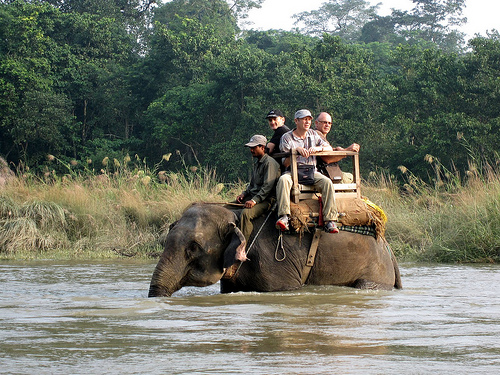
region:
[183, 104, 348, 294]
Four men riding an elephant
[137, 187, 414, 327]
The elephant is walking through water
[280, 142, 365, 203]
This is a wood structure atop an elephant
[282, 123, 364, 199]
The people riding the elephant are inside of the wood structure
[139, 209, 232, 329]
The elephants trunk is in the water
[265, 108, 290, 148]
This man is wearing a black shirt and ball cap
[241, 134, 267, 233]
This man is steering the elephant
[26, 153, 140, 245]
The weeds are tall and brown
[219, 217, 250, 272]
The elephants left ear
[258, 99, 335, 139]
The men are looking the same direction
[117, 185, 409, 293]
An elephant in the water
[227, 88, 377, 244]
4 men riding the elephant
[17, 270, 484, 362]
The water is calm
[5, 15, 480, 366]
Photo taken during the day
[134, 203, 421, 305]
The elephant is grayish brown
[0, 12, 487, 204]
Green leaves on the trees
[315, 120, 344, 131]
Glasses on the man's face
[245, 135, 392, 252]
Wooden saddle on the elephant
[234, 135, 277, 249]
Man navigating the elephant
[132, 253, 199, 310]
Elephant's trunk in the water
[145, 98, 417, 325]
An elephant in water.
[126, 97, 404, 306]
An elephant giving passengers a ride across the water.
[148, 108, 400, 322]
Three passengers ride an elephant.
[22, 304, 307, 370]
A body of water.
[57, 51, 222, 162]
A wooded area.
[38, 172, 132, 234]
The tall grass.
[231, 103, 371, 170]
Three out of four men wearing hats.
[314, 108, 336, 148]
A man wearing glasses.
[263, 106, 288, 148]
A man wearing a black hat.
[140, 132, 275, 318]
A man steering an elephant in the water.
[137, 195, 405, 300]
Large elephant in water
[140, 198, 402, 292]
Large elephant is wet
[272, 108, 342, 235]
Man wearing gray hat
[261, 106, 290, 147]
Man wearing black hat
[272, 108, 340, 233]
Man carrying black briefcase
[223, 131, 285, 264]
Man wearing green pants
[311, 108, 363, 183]
Man holding onto wooden crate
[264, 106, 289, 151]
Man wearing black shirt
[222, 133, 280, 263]
Man wearing button down shirt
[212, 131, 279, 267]
Man wearing gray cap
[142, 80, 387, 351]
four men riding a elephant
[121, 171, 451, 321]
a elephant in water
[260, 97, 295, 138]
a man wearing a black hat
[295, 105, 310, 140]
a man wearing a white hat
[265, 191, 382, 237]
a blanket across a elephant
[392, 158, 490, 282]
tall grass next to water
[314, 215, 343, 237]
a man wearing grey and red shoes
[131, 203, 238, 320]
a elephants trunk in water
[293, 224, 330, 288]
a strap around a elephants stomach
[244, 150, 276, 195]
a man wearing a green shirt